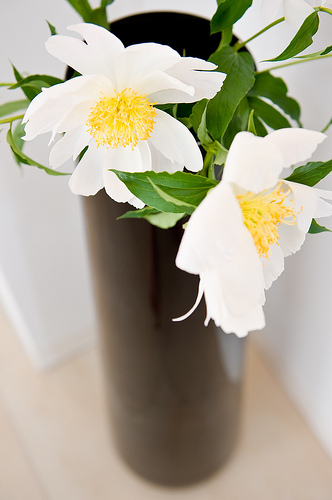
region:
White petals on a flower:
[213, 260, 252, 301]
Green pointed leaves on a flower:
[101, 161, 192, 207]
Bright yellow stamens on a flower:
[241, 193, 289, 251]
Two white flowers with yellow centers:
[62, 55, 298, 256]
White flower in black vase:
[67, 62, 154, 299]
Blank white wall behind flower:
[259, 225, 324, 311]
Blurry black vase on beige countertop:
[106, 404, 266, 492]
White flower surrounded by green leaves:
[192, 60, 293, 210]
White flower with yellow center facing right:
[215, 137, 322, 288]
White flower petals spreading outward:
[45, 10, 227, 102]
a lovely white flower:
[175, 122, 328, 346]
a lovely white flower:
[21, 22, 227, 203]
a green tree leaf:
[111, 164, 220, 217]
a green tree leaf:
[207, 36, 251, 152]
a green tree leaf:
[285, 158, 329, 186]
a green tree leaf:
[309, 216, 328, 240]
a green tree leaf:
[262, 7, 323, 66]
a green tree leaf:
[209, 0, 250, 36]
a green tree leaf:
[116, 203, 162, 222]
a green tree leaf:
[8, 71, 58, 95]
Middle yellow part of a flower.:
[80, 89, 159, 152]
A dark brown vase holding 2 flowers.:
[62, 10, 259, 489]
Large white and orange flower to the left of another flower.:
[21, 21, 227, 211]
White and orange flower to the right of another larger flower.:
[171, 128, 330, 338]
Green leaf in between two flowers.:
[108, 168, 217, 217]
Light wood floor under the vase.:
[1, 293, 331, 498]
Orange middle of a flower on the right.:
[231, 178, 306, 262]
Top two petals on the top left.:
[40, 22, 126, 76]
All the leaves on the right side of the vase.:
[106, 0, 330, 235]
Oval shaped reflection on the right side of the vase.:
[216, 324, 245, 387]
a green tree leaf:
[246, 110, 258, 134]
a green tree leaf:
[251, 68, 306, 125]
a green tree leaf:
[252, 102, 287, 131]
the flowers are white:
[59, 35, 308, 284]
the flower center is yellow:
[92, 96, 151, 145]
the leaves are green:
[206, 52, 270, 144]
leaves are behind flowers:
[199, 55, 308, 323]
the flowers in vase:
[77, 7, 266, 405]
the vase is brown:
[86, 248, 257, 497]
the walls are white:
[4, 175, 105, 378]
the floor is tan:
[18, 377, 123, 493]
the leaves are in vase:
[156, 8, 283, 135]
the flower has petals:
[206, 172, 311, 275]